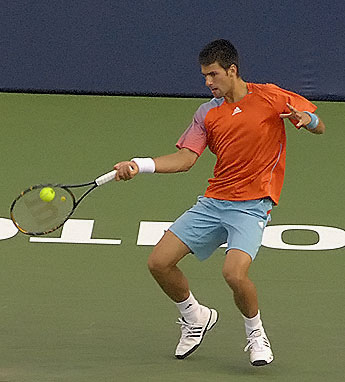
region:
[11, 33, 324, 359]
The man is swinging his tennis racket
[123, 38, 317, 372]
The man is a tennis player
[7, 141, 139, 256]
The tennis racket is black with a white handle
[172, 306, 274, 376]
The man wears white shoes with black markings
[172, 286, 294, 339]
The man wears white socks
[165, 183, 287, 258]
The man wears light blue shorts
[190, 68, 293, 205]
The man wears an orange t-shirt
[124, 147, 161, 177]
The man has a white wrist band on his right hand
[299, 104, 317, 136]
The man has a light blue wrist band on his left hand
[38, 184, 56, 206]
The tennis ball is neon green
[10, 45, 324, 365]
Man hitting the tennis ball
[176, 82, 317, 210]
Orange shirt man is wearing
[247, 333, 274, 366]
Left white and black tennis shoe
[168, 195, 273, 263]
Blue shorts worn by the tennis player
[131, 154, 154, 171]
White wrist band on player's right wrist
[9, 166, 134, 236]
racket held by the tennis player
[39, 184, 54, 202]
Tennis ball being hit with the racket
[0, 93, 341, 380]
Green and white tennis court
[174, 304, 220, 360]
Right white and black tennis shoe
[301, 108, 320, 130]
Blue wrist band on man's left wrist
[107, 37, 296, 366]
Man playing a game of tennis.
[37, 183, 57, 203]
yellow green ball in midair.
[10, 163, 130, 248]
Wilson racquet in the hand.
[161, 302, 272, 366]
White shoes on the feet.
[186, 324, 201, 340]
black stripes on the shoe.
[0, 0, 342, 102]
Blue wall in the background.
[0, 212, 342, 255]
White letters on the ground.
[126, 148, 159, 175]
White sweatband on the wrist.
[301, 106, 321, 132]
Blue sweatband on the wrist.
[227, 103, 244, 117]
White logo on the shirt.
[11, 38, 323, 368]
a tennis player about to hit a ball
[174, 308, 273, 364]
white shoes with black lines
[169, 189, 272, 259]
man wearing blue shorts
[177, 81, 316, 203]
man wearing an orange shirt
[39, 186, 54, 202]
a yellow ball on a tennis racket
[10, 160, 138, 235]
a man holding a tennis racket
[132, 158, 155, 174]
man wearing a white wristband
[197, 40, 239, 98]
man with short brown hair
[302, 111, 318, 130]
man wearing a blue wristband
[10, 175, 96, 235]
a black and golden tennis racket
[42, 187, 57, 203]
yellow tennis ball in air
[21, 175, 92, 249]
tennis ball being hit by a tennis racket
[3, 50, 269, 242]
man holding tennis racket with his right hand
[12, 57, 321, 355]
man hitting a tennis ball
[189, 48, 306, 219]
man is wearing an orange shirt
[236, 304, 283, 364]
white shoe with black strips on the side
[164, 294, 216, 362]
white shoe with black strips on the side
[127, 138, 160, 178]
white wrist band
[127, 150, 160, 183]
wristband on right hand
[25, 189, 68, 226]
"w" can be seen in the strings of racket